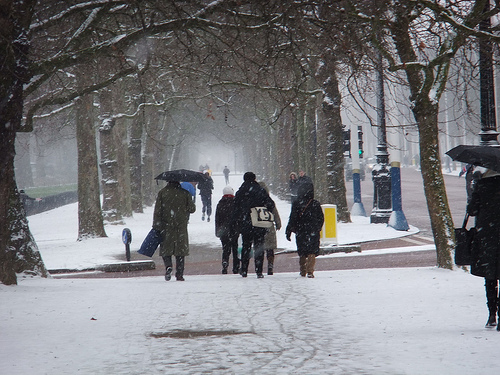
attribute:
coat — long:
[151, 186, 193, 256]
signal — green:
[357, 147, 364, 156]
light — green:
[350, 126, 367, 163]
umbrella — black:
[148, 166, 213, 182]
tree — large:
[2, 12, 69, 284]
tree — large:
[66, 17, 116, 249]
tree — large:
[383, 21, 462, 275]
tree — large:
[293, 30, 360, 221]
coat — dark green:
[152, 184, 197, 264]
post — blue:
[386, 162, 409, 231]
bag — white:
[249, 205, 277, 230]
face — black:
[255, 205, 271, 222]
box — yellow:
[316, 204, 348, 248]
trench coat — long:
[150, 183, 197, 258]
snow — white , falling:
[253, 253, 386, 350]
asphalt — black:
[411, 179, 420, 214]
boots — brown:
[294, 236, 338, 301]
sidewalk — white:
[147, 265, 388, 334]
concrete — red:
[343, 248, 443, 269]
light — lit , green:
[357, 149, 364, 159]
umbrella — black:
[444, 142, 484, 171]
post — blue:
[349, 168, 364, 215]